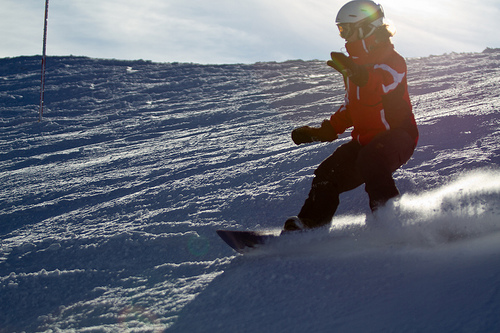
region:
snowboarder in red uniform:
[281, 3, 419, 240]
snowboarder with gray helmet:
[274, 5, 425, 246]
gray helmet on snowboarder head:
[336, 0, 388, 55]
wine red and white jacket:
[325, 37, 417, 140]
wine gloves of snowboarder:
[289, 51, 368, 151]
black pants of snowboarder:
[271, 122, 410, 239]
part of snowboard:
[216, 226, 291, 256]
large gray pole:
[34, 2, 52, 124]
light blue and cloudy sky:
[3, 2, 495, 70]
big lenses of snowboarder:
[337, 24, 367, 36]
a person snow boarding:
[226, 7, 426, 265]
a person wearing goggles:
[308, 0, 406, 62]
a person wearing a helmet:
[323, 7, 393, 49]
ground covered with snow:
[18, 104, 238, 251]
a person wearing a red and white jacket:
[325, 17, 427, 136]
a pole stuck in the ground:
[28, 6, 57, 131]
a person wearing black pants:
[293, 16, 410, 235]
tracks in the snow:
[17, 79, 251, 266]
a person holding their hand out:
[265, 11, 412, 114]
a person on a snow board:
[203, 8, 398, 261]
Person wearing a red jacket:
[338, 50, 399, 135]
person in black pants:
[309, 133, 398, 218]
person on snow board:
[216, 199, 324, 252]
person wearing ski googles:
[338, 18, 354, 43]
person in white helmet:
[333, 2, 379, 34]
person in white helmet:
[316, 11, 401, 47]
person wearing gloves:
[284, 107, 318, 154]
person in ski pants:
[314, 160, 424, 216]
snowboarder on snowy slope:
[225, 4, 417, 251]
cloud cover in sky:
[3, 1, 497, 61]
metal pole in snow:
[38, 1, 50, 115]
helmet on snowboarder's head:
[334, 2, 387, 32]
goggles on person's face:
[336, 22, 357, 41]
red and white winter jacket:
[329, 44, 406, 146]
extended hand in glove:
[325, 52, 386, 85]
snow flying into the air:
[260, 182, 494, 261]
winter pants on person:
[300, 133, 420, 226]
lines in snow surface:
[9, 68, 330, 229]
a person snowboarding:
[114, 8, 499, 305]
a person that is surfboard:
[161, 1, 488, 319]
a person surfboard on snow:
[57, 6, 492, 328]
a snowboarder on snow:
[107, 15, 482, 330]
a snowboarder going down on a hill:
[77, 11, 479, 291]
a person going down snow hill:
[123, 6, 499, 286]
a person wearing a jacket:
[222, 1, 444, 236]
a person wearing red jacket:
[276, 1, 457, 184]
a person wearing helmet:
[322, 4, 424, 59]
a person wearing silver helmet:
[324, 3, 439, 68]